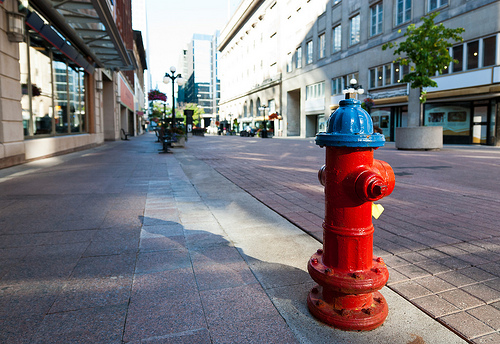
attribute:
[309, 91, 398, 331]
hydrant — red, metal, clean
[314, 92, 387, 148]
top — blue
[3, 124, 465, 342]
sidewalk — red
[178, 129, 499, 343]
floor — red, brick, downtown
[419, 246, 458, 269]
bricks — brick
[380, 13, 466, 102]
tree — green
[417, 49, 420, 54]
leaf — green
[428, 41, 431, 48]
leaf — green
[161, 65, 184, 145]
lamp post — off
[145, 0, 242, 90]
sky — white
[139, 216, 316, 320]
shadow — long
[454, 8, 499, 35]
wall — beige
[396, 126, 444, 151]
planter — concrete, cement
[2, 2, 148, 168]
building — downtown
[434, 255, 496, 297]
pavers — brick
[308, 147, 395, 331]
fire hydrant bottom — red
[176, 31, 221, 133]
building — glass, skyscraper, tall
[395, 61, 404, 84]
lights — on